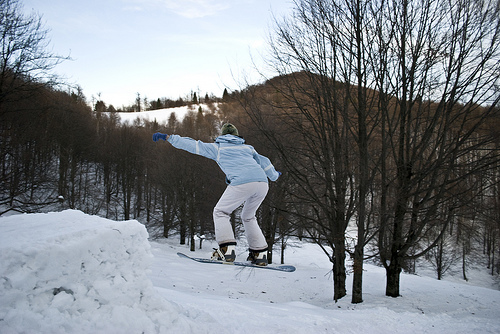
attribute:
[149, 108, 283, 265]
person — skiing, jumping, snowboarding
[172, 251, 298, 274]
snowboard — blue, dark, jumping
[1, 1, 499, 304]
trees — empty, bare, dark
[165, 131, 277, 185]
jacket — blue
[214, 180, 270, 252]
pants — white, sporty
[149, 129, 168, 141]
glove — blue, dark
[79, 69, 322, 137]
hill — standing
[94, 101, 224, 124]
snow — white, piled, packed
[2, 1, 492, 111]
sky — blue, clear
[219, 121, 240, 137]
hat — green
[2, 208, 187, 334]
snow — piled